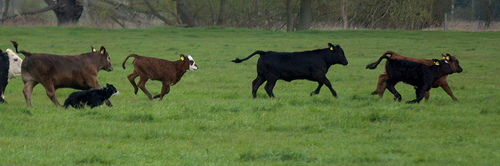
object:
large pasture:
[0, 24, 499, 166]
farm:
[0, 24, 499, 166]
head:
[325, 41, 349, 66]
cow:
[229, 42, 351, 99]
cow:
[119, 52, 203, 101]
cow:
[8, 39, 116, 109]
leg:
[21, 80, 39, 107]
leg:
[383, 78, 404, 102]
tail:
[229, 49, 267, 64]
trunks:
[44, 0, 86, 28]